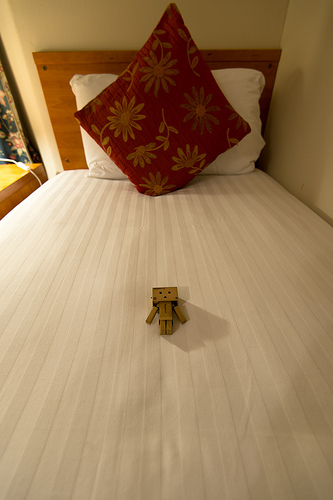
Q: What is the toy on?
A: Bed.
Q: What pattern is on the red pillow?
A: Floral.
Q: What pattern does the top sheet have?
A: Stripes.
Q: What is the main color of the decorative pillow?
A: Red.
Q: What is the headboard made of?
A: Wood.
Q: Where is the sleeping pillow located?
A: Behind the decorative pillow.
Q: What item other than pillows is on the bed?
A: Wooden toy.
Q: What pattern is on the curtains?
A: Floral.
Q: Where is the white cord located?
A: Bedside table.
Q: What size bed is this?
A: Twin.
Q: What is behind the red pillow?
A: White pillow.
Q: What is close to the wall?
A: Headboard.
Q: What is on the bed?
A: Blanket.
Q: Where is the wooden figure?
A: On the bed.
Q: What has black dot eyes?
A: Wooden figure.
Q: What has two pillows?
A: The bed.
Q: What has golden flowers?
A: Pillow.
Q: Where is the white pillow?
A: With red pillow.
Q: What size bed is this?
A: Twin.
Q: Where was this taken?
A: On a bed.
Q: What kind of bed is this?
A: Twin.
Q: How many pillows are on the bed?
A: Two.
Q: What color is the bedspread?
A: White.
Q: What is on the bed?
A: A toy.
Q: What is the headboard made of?
A: Wood.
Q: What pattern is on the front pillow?
A: Flowers.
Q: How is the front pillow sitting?
A: On a point.